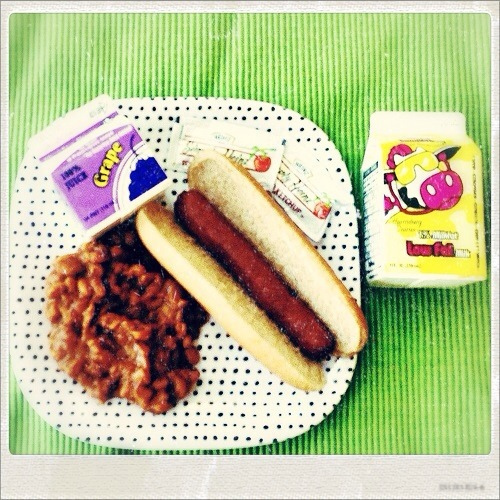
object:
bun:
[133, 202, 325, 390]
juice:
[26, 94, 172, 240]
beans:
[173, 377, 187, 400]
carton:
[28, 93, 175, 242]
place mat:
[8, 12, 492, 452]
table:
[7, 14, 491, 454]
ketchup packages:
[170, 122, 285, 193]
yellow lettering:
[93, 172, 111, 189]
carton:
[360, 111, 488, 289]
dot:
[299, 127, 304, 132]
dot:
[276, 116, 283, 120]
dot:
[335, 167, 340, 172]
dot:
[167, 116, 173, 121]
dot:
[338, 266, 345, 271]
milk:
[358, 111, 489, 289]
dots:
[218, 413, 221, 418]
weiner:
[173, 189, 336, 360]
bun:
[186, 153, 367, 355]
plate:
[6, 94, 361, 451]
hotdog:
[137, 152, 372, 393]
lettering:
[433, 242, 442, 257]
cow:
[383, 142, 462, 224]